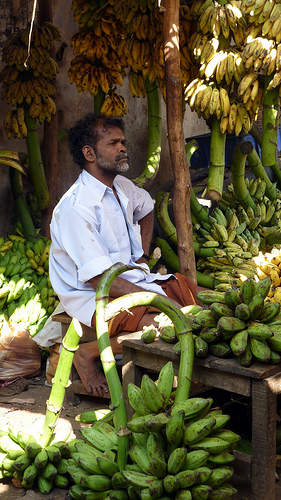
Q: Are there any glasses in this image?
A: No, there are no glasses.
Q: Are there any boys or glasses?
A: No, there are no glasses or boys.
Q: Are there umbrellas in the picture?
A: No, there are no umbrellas.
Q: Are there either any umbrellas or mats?
A: No, there are no umbrellas or mats.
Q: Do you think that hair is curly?
A: Yes, the hair is curly.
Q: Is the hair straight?
A: No, the hair is curly.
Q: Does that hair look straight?
A: No, the hair is curly.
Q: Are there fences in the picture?
A: Yes, there is a fence.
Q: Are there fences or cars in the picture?
A: Yes, there is a fence.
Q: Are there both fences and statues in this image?
A: No, there is a fence but no statues.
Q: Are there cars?
A: No, there are no cars.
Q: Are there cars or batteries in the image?
A: No, there are no cars or batteries.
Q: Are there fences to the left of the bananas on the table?
A: Yes, there is a fence to the left of the bananas.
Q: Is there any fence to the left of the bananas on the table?
A: Yes, there is a fence to the left of the bananas.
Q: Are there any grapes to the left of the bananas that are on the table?
A: No, there is a fence to the left of the bananas.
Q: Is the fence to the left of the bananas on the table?
A: Yes, the fence is to the left of the bananas.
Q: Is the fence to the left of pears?
A: No, the fence is to the left of the bananas.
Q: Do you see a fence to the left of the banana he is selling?
A: Yes, there is a fence to the left of the banana.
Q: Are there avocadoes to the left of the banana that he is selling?
A: No, there is a fence to the left of the banana.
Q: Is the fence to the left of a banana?
A: Yes, the fence is to the left of a banana.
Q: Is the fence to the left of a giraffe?
A: No, the fence is to the left of a banana.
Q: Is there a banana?
A: Yes, there are bananas.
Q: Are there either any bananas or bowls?
A: Yes, there are bananas.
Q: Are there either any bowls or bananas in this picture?
A: Yes, there are bananas.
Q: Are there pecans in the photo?
A: No, there are no pecans.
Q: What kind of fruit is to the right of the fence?
A: The fruits are bananas.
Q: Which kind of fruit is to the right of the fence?
A: The fruits are bananas.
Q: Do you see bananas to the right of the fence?
A: Yes, there are bananas to the right of the fence.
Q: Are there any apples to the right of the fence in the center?
A: No, there are bananas to the right of the fence.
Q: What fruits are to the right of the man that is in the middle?
A: The fruits are bananas.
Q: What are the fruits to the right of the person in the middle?
A: The fruits are bananas.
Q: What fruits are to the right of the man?
A: The fruits are bananas.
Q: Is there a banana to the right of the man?
A: Yes, there are bananas to the right of the man.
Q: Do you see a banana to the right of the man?
A: Yes, there are bananas to the right of the man.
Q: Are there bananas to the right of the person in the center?
A: Yes, there are bananas to the right of the man.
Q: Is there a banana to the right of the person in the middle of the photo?
A: Yes, there are bananas to the right of the man.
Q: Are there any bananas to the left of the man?
A: No, the bananas are to the right of the man.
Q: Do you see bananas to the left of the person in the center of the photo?
A: No, the bananas are to the right of the man.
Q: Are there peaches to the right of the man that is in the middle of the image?
A: No, there are bananas to the right of the man.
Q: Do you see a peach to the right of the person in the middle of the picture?
A: No, there are bananas to the right of the man.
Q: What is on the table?
A: The bananas are on the table.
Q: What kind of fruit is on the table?
A: The fruits are bananas.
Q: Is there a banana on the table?
A: Yes, there are bananas on the table.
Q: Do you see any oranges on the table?
A: No, there are bananas on the table.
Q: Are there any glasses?
A: No, there are no glasses.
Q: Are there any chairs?
A: No, there are no chairs.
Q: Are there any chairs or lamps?
A: No, there are no chairs or lamps.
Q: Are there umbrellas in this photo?
A: No, there are no umbrellas.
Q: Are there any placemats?
A: No, there are no placemats.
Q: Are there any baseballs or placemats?
A: No, there are no placemats or baseballs.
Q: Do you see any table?
A: Yes, there is a table.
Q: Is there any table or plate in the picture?
A: Yes, there is a table.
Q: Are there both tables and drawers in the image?
A: No, there is a table but no drawers.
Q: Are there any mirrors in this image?
A: No, there are no mirrors.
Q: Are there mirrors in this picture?
A: No, there are no mirrors.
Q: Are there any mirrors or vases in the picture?
A: No, there are no mirrors or vases.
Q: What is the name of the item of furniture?
A: The piece of furniture is a table.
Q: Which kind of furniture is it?
A: The piece of furniture is a table.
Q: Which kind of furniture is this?
A: This is a table.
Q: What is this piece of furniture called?
A: This is a table.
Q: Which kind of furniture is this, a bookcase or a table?
A: This is a table.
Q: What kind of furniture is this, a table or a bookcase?
A: This is a table.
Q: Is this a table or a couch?
A: This is a table.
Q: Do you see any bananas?
A: Yes, there is a banana.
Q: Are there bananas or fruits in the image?
A: Yes, there is a banana.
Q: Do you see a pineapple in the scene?
A: No, there are no pineapples.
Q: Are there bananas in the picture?
A: Yes, there is a banana.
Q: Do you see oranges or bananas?
A: Yes, there is a banana.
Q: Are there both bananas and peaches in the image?
A: No, there is a banana but no peaches.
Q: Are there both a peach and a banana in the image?
A: No, there is a banana but no peaches.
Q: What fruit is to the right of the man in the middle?
A: The fruit is a banana.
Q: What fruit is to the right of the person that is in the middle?
A: The fruit is a banana.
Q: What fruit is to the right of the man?
A: The fruit is a banana.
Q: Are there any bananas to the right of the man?
A: Yes, there is a banana to the right of the man.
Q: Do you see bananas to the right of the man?
A: Yes, there is a banana to the right of the man.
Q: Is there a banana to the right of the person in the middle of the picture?
A: Yes, there is a banana to the right of the man.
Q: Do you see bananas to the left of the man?
A: No, the banana is to the right of the man.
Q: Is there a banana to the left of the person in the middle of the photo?
A: No, the banana is to the right of the man.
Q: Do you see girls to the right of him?
A: No, there is a banana to the right of the man.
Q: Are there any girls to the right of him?
A: No, there is a banana to the right of the man.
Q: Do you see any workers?
A: No, there are no workers.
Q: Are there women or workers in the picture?
A: No, there are no workers or women.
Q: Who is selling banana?
A: The man is selling banana.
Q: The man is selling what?
A: The man is selling banana.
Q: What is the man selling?
A: The man is selling banana.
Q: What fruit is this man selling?
A: The man is selling banana.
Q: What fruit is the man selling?
A: The man is selling banana.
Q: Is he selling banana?
A: Yes, the man is selling banana.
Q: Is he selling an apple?
A: No, the man is selling banana.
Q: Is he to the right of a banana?
A: No, the man is to the left of a banana.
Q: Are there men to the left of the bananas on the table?
A: Yes, there is a man to the left of the bananas.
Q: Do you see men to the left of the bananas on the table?
A: Yes, there is a man to the left of the bananas.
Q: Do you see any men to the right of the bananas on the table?
A: No, the man is to the left of the bananas.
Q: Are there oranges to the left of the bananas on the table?
A: No, there is a man to the left of the bananas.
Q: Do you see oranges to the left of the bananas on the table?
A: No, there is a man to the left of the bananas.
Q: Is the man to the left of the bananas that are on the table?
A: Yes, the man is to the left of the bananas.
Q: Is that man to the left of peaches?
A: No, the man is to the left of the bananas.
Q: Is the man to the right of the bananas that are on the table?
A: No, the man is to the left of the bananas.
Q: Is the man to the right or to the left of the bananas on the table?
A: The man is to the left of the bananas.